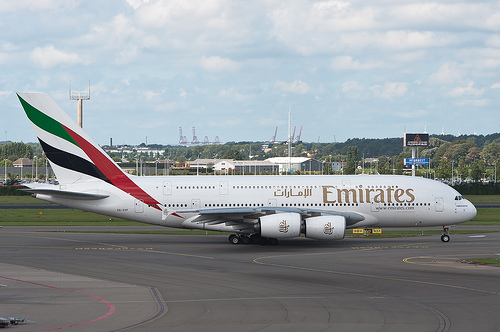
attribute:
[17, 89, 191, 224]
logo — colorful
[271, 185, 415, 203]
logo — gold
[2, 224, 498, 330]
runway — gray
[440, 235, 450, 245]
wheel — black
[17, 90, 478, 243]
plane — large, parked, white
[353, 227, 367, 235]
barrier — yellow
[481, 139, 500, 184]
tree — green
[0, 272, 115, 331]
paint — red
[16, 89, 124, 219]
tail — colorful, red, green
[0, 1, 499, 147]
sky — cloudy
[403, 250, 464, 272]
paint — yellow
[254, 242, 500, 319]
line — yellow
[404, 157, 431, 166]
sign — blue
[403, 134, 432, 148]
sign — black